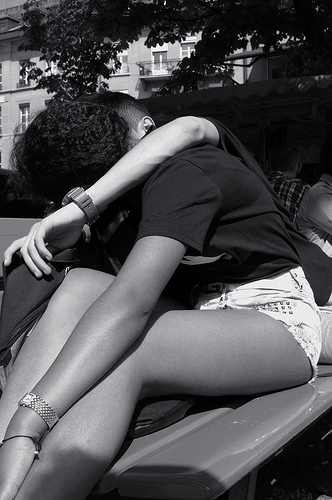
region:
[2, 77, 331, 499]
A couple cuddling with each other.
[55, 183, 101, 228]
Watch on the wrist.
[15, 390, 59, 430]
Metal band on the watch.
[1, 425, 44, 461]
Bracelet on the wrist.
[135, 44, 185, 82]
Balcony on the building.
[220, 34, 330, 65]
Awning on the building.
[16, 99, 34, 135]
Window on the building.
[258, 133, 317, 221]
Man in a plaid shirt.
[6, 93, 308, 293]
T-shirt on the girl.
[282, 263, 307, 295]
Belt hoop on the shorts.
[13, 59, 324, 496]
Two people sitting down together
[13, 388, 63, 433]
The woman has on a watch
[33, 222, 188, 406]
The arm of the woman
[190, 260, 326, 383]
The woman has on shorts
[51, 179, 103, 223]
The man is wearing a watch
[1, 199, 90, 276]
The hand of the man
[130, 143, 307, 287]
The woman is wearing a black shirt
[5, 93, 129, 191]
The woman has black hair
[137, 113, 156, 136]
The ear of the man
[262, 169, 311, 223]
The man has on a plaid shirt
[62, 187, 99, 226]
a plastic wrist watch on a wrist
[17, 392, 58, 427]
an elegant wrist watch on a wrist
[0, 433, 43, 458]
a little bracelet on a woman's arm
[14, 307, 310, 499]
an attractive leg of a woman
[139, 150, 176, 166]
veins visible through the person's skin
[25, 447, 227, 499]
a shadow on the scene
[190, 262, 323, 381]
a pair of shorts on a woman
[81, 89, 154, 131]
short hair of a man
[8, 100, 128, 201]
curly hair of a woman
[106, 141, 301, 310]
a dark shirt on a woman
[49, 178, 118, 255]
boy is wearing a watch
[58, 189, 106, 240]
boy is wearing a watch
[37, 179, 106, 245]
boy is wearing a watch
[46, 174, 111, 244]
boy is wearing a watch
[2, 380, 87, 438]
girl is wearing a watch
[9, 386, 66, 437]
girl is wearing a watch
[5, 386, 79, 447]
girl is wearing a watch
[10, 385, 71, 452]
girl is wearing a watch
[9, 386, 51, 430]
girl is wearing a watch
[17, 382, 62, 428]
Girl wearing a watch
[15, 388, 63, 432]
Girl is wearing a watch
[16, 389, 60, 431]
Girl wearing a wrist watch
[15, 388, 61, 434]
Girl is wearing a wrist watch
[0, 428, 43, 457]
Girl is wearing a bracelet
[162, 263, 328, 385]
Girl wearing shorts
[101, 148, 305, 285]
Girl wearing a shirt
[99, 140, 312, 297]
Girl is wearing a shirt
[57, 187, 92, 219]
watch worn by woman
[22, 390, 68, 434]
watch worn by woman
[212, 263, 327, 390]
shorts worn by young woman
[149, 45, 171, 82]
window in tan colored building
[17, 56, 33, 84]
window in tan colored building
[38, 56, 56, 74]
window in tan colored building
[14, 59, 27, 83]
a window on a building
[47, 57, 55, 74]
a window on a building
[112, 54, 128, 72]
a window on a building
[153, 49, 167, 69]
a window on a building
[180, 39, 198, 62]
a window on a building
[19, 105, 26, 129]
a window on a building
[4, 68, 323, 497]
a person is sitting down